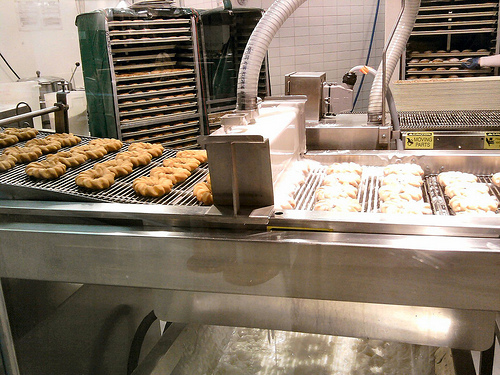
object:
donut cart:
[78, 9, 217, 158]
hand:
[456, 53, 480, 73]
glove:
[459, 54, 481, 72]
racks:
[403, 46, 483, 78]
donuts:
[403, 48, 481, 76]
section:
[209, 95, 312, 218]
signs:
[13, 0, 61, 33]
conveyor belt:
[390, 107, 499, 133]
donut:
[132, 178, 172, 198]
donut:
[46, 148, 85, 166]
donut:
[308, 194, 369, 216]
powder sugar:
[316, 197, 356, 210]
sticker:
[403, 130, 435, 150]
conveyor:
[391, 108, 484, 132]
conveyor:
[16, 177, 76, 194]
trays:
[115, 68, 193, 80]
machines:
[394, 108, 499, 139]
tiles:
[324, 22, 355, 42]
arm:
[460, 53, 499, 70]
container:
[36, 73, 69, 88]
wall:
[38, 41, 68, 64]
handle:
[68, 63, 80, 91]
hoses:
[234, 16, 282, 114]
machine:
[282, 69, 354, 125]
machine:
[0, 110, 474, 319]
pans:
[120, 114, 197, 129]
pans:
[411, 68, 473, 78]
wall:
[258, 0, 382, 117]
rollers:
[44, 175, 73, 194]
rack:
[108, 17, 195, 139]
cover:
[79, 39, 112, 105]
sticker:
[406, 131, 439, 150]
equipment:
[202, 102, 499, 331]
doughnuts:
[118, 64, 192, 93]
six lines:
[0, 126, 223, 204]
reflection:
[184, 238, 286, 285]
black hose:
[124, 307, 158, 373]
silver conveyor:
[0, 115, 483, 338]